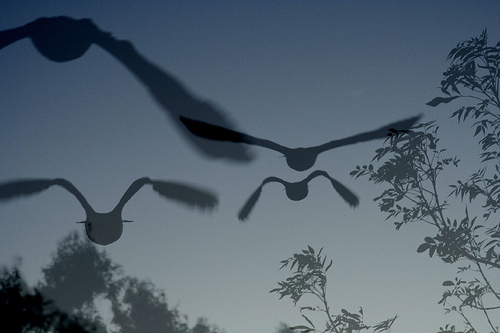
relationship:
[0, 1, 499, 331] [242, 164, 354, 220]
sky behind bird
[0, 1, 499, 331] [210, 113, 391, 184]
sky behind bird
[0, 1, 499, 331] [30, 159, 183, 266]
sky behind bird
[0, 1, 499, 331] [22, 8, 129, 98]
sky behind bird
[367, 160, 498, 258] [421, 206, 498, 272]
leaves on branch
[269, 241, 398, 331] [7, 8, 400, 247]
branch near birds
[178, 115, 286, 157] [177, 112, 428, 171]
wing flapping on bird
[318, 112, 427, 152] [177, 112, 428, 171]
wing flapping on bird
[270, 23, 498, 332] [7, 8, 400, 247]
plants beside birds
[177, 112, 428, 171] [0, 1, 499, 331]
bird in sky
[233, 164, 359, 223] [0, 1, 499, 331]
bird in sky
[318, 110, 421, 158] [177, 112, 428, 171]
wing on bird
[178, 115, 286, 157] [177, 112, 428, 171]
wing on bird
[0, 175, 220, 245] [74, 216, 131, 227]
bird carrying stick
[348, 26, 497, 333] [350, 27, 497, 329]
leaves on tree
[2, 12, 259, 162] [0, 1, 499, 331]
bird flying in sky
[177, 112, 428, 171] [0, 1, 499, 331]
bird flying in sky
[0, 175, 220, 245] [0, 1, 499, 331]
bird flying in sky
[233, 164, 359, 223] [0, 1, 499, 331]
bird flying in sky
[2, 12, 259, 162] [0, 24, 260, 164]
bird flapping wings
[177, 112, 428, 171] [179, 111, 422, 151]
bird flapping wings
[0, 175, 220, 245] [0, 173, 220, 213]
bird flapping wings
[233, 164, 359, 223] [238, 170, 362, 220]
bird flapping wings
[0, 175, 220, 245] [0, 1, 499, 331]
bird in sky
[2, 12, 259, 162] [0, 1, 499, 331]
bird in sky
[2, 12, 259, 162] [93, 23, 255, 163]
bird flapping wing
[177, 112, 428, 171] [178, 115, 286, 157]
bird flapping wing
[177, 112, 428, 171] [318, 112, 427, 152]
bird flapping wing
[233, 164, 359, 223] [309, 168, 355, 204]
bird flapping wing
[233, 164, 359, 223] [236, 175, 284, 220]
bird flapping wing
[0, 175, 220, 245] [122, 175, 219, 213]
bird flapping wing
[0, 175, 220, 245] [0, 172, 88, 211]
bird flapping wing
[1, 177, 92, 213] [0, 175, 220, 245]
wing of bird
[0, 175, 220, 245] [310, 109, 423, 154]
bird with wing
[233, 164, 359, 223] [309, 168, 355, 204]
bird with wing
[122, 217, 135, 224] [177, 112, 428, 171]
line from bird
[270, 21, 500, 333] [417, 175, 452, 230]
plants have stems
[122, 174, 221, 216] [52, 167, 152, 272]
wing of a bird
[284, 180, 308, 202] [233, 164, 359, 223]
body of a bird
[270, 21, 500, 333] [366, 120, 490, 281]
plants has leaves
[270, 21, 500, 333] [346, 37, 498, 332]
plants has leaves